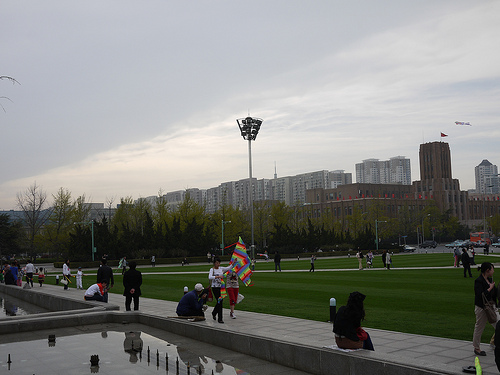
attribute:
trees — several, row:
[6, 181, 473, 258]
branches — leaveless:
[1, 64, 25, 118]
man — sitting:
[174, 282, 207, 322]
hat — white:
[192, 282, 206, 292]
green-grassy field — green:
[108, 243, 498, 318]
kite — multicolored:
[217, 235, 254, 304]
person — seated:
[318, 266, 390, 347]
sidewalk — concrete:
[54, 270, 494, 373]